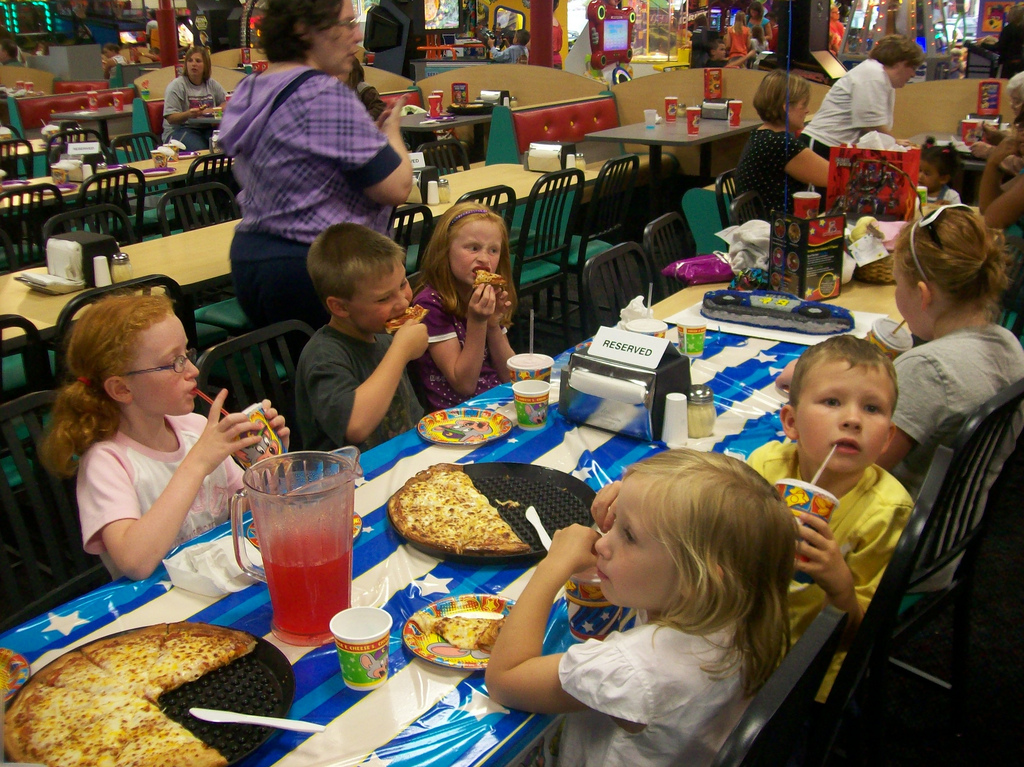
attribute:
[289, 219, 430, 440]
person — sitting down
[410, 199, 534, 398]
person — sitting down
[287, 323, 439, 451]
shirt — grey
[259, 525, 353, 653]
drink — red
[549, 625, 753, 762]
shirt — white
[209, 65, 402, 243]
shirt — purple